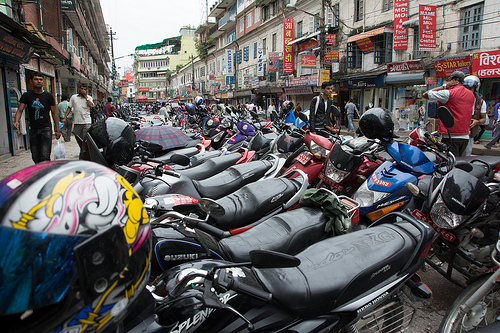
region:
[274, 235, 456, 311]
motorcycle parked in a row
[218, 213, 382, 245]
motorcycle parked in a row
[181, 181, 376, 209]
motorcycle parked in a row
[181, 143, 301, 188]
motorcycle parked in a row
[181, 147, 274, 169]
motorcycle parked in a row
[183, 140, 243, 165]
motorcycle parked in a row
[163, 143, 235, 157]
motorcycle parked in a row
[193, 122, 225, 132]
motorcycle parked in a row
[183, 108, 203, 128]
motorcycle parked in a row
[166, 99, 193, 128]
motorcycle parked in a row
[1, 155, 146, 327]
colorful motorcycle helmet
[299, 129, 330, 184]
light of the red motorcycle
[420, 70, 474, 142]
man in red vest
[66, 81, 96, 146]
man in white shirt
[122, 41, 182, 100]
yellow building with windows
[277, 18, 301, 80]
sign on the building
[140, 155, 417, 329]
multiple black motorcycles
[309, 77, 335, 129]
man with black coat on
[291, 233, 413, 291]
black seat of motorcycle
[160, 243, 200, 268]
suzuki logo on motorcycle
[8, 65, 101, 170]
People in the background are walking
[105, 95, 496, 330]
A large group of motobikes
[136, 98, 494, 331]
The Motorbikes are parked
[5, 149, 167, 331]
A helmet in the foreground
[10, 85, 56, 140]
Person is wearing a black shirt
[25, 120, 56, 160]
Person is wearing black pants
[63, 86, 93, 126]
Person is wearing a white shirt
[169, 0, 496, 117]
Building in the background are connected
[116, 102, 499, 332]
Motorbikes are in two rows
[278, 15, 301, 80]
Building has a red sign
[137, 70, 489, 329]
several motorcycles parked together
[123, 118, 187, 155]
a open umbrella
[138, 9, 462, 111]
several signs hanging from buildings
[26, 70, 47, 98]
a man with black hair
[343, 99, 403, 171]
a black helmet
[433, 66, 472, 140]
a man wearing a red and white shirt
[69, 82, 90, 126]
a man wearing a white shirt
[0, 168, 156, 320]
a helmet with a blue face shield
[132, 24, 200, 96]
a yellow building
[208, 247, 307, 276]
rear view mirror on a motorcycle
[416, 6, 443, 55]
Red and white sign on side of building.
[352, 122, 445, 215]
Blue motorcycle parked on street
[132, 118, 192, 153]
Plaid umbrella on street.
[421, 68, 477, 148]
Man wearing a red vest.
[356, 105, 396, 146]
Black helmet sitting on motorcycle.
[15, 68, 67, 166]
Man carrying white shopping bag.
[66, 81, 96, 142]
Man wearing watch on left wrist.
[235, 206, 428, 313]
Black motorcycle seat.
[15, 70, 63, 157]
Black t-shirt on man.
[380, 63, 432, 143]
Store front in background.